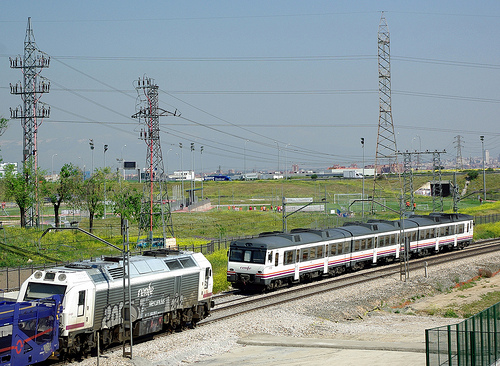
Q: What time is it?
A: Afternoon.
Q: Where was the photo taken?
A: Outside somewhere.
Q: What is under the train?
A: Tracks.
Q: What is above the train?
A: The sky.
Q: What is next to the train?
A: Gravel.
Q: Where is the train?
A: On the tracks.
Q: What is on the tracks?
A: Trains.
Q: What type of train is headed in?
A: A passenger train.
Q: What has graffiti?
A: The side of a train.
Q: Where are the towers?
A: In grass near the train tracks.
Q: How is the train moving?
A: On tracks.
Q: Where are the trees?
A: On the hill near the tracks.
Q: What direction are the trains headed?
A: Towards each other.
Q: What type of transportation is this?
A: Train.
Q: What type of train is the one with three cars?
A: A passenger train.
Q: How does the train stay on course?
A: Railroad tracks.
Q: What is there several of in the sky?
A: Power lines.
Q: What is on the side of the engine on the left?
A: Graffiti.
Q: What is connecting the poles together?
A: Electrical wires.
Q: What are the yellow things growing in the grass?
A: Wildflowers.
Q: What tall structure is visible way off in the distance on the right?
A: A skyscraper.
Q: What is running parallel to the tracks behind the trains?
A: A fence.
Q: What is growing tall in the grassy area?
A: Trees.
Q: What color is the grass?
A: Green.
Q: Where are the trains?
A: On the tracks.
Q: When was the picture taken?
A: Daytime.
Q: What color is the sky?
A: Blue.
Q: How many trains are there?
A: Two.